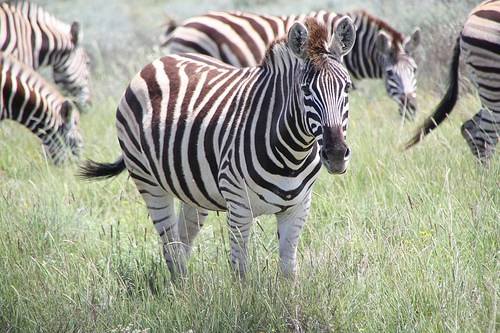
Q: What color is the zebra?
A: Black and white.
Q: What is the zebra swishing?
A: Tail.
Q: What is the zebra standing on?
A: Grass.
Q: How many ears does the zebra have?
A: Two.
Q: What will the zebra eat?
A: Grass.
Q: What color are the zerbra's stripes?
A: Black and white.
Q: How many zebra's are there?
A: Five.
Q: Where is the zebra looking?
A: Camera.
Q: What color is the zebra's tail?
A: Black.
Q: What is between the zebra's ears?
A: Mane.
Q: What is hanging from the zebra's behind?
A: Tail.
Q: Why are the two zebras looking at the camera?
A: Curiosity.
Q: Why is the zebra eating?
A: Hungry.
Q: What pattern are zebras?
A: Striped.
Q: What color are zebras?
A: Black and white.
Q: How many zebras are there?
A: Five.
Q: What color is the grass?
A: Green.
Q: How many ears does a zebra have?
A: Two.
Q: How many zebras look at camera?
A: Two.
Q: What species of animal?
A: Zebra.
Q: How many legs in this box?
A: Four.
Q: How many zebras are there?
A: More than three.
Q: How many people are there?
A: None.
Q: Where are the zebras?
A: In a field.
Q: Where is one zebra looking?
A: At the camera.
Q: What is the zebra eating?
A: Grass.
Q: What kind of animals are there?
A: Zebras.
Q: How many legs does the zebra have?
A: Four.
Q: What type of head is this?
A: Zebra.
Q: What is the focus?
A: Zebras.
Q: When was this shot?
A: Daytime.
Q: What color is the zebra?
A: Black and white.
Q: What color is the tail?
A: Black.